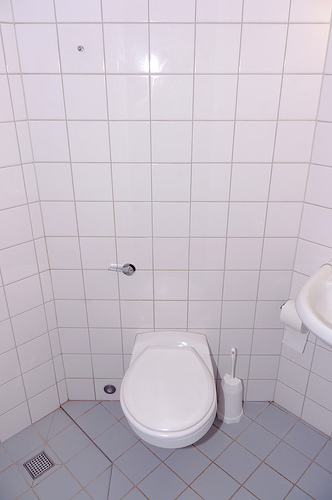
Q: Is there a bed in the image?
A: No, there are no beds.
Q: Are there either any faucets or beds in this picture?
A: No, there are no beds or faucets.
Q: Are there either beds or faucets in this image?
A: No, there are no beds or faucets.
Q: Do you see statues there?
A: No, there are no statues.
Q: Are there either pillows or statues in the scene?
A: No, there are no statues or pillows.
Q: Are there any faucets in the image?
A: No, there are no faucets.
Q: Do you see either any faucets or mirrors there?
A: No, there are no faucets or mirrors.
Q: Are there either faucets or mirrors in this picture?
A: No, there are no faucets or mirrors.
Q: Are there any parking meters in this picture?
A: No, there are no parking meters.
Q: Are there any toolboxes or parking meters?
A: No, there are no parking meters or toolboxes.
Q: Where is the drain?
A: The drain is on the floor.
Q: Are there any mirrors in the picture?
A: No, there are no mirrors.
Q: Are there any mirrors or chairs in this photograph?
A: No, there are no mirrors or chairs.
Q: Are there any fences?
A: No, there are no fences.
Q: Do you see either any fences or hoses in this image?
A: No, there are no fences or hoses.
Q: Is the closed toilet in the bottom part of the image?
A: Yes, the toilet is in the bottom of the image.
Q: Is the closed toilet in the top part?
A: No, the toilet is in the bottom of the image.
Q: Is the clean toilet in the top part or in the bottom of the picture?
A: The toilet is in the bottom of the image.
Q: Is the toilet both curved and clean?
A: Yes, the toilet is curved and clean.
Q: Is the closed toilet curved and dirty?
A: No, the toilet is curved but clean.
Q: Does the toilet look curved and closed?
A: Yes, the toilet is curved and closed.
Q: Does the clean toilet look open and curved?
A: No, the toilet is curved but closed.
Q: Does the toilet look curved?
A: Yes, the toilet is curved.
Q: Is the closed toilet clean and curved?
A: Yes, the toilet is clean and curved.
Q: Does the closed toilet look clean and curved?
A: Yes, the toilet is clean and curved.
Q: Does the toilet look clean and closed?
A: Yes, the toilet is clean and closed.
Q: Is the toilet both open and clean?
A: No, the toilet is clean but closed.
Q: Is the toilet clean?
A: Yes, the toilet is clean.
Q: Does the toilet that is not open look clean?
A: Yes, the toilet is clean.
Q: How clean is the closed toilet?
A: The toilet is clean.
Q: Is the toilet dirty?
A: No, the toilet is clean.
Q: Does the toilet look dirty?
A: No, the toilet is clean.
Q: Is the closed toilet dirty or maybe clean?
A: The toilet is clean.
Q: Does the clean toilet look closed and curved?
A: Yes, the toilet is closed and curved.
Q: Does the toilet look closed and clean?
A: Yes, the toilet is closed and clean.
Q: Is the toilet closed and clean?
A: Yes, the toilet is closed and clean.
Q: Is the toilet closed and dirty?
A: No, the toilet is closed but clean.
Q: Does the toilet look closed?
A: Yes, the toilet is closed.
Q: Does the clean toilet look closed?
A: Yes, the toilet is closed.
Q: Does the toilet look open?
A: No, the toilet is closed.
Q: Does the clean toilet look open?
A: No, the toilet is closed.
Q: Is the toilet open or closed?
A: The toilet is closed.